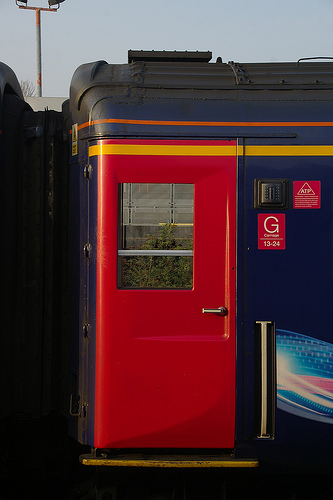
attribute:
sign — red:
[254, 213, 288, 251]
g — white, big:
[251, 213, 290, 245]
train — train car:
[72, 85, 330, 423]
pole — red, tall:
[12, 1, 70, 99]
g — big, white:
[262, 214, 279, 233]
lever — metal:
[199, 306, 229, 316]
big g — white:
[257, 215, 282, 232]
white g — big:
[258, 215, 287, 236]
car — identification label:
[254, 210, 287, 249]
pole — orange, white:
[18, 4, 59, 96]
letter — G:
[259, 213, 285, 234]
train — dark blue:
[28, 37, 332, 402]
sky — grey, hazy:
[0, 0, 333, 97]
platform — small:
[81, 451, 259, 471]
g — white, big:
[263, 212, 282, 236]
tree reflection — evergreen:
[128, 225, 191, 284]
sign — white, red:
[250, 201, 289, 255]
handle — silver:
[198, 302, 220, 317]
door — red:
[91, 138, 238, 450]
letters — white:
[257, 211, 283, 250]